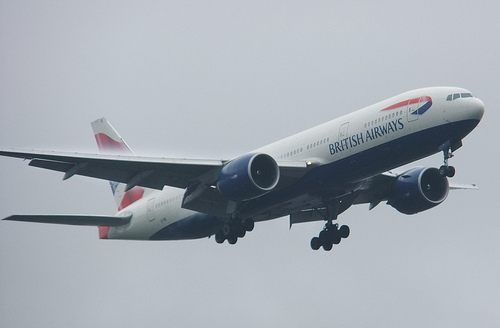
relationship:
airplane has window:
[0, 87, 485, 251] [379, 116, 382, 123]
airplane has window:
[0, 87, 485, 251] [399, 108, 404, 114]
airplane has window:
[0, 87, 485, 251] [315, 140, 318, 145]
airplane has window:
[0, 87, 485, 251] [327, 135, 332, 142]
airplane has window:
[0, 87, 485, 251] [306, 145, 311, 150]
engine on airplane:
[212, 153, 278, 202] [0, 87, 485, 251]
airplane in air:
[0, 87, 485, 251] [0, 0, 500, 327]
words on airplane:
[327, 115, 406, 158] [0, 87, 485, 251]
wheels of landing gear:
[211, 217, 376, 270] [440, 133, 461, 185]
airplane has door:
[0, 87, 485, 251] [406, 93, 419, 122]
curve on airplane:
[378, 95, 433, 115] [0, 87, 485, 251]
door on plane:
[406, 97, 421, 122] [5, 61, 487, 285]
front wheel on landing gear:
[439, 165, 456, 178] [217, 166, 456, 252]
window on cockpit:
[445, 90, 453, 102] [443, 85, 483, 120]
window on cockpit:
[451, 91, 460, 99] [443, 85, 483, 120]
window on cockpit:
[461, 91, 472, 98] [443, 85, 483, 120]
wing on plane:
[0, 148, 317, 216] [106, 66, 450, 263]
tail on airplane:
[87, 116, 153, 238] [0, 87, 485, 251]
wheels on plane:
[305, 220, 357, 253] [14, 96, 496, 238]